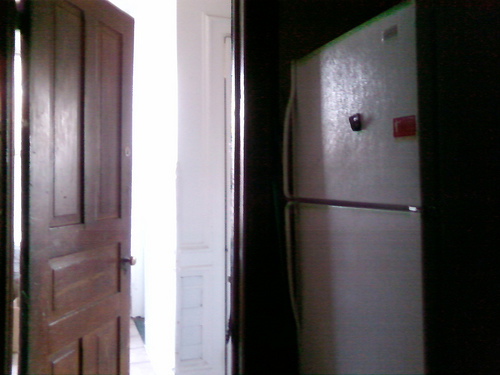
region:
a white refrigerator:
[272, 9, 424, 374]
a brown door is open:
[11, 4, 141, 374]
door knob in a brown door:
[119, 246, 144, 273]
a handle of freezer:
[273, 63, 303, 200]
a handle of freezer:
[275, 200, 308, 333]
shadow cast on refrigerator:
[270, 40, 355, 372]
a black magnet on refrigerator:
[336, 105, 371, 140]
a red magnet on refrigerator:
[386, 109, 422, 145]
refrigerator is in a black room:
[243, 6, 492, 373]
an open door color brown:
[11, 6, 139, 373]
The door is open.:
[31, 12, 161, 372]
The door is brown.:
[37, 86, 134, 373]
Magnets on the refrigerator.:
[334, 102, 427, 157]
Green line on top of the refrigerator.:
[286, 0, 436, 78]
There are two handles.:
[263, 95, 313, 321]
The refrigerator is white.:
[291, 54, 441, 374]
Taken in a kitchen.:
[8, 9, 496, 374]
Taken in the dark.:
[232, 7, 494, 373]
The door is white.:
[175, 23, 229, 363]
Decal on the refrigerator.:
[369, 14, 420, 59]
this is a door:
[20, 94, 126, 370]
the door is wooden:
[17, 110, 128, 373]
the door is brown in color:
[26, 140, 121, 370]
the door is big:
[22, 111, 132, 371]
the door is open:
[28, 6, 225, 370]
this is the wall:
[142, 3, 217, 211]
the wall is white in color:
[154, 222, 175, 257]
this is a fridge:
[283, 50, 436, 367]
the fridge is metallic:
[315, 261, 411, 353]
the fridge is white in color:
[321, 251, 391, 334]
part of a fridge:
[345, 282, 382, 348]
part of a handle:
[272, 242, 312, 310]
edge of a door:
[109, 271, 138, 311]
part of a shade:
[305, 232, 387, 307]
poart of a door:
[184, 257, 219, 337]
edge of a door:
[141, 252, 175, 299]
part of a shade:
[321, 255, 374, 322]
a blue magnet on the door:
[332, 105, 371, 140]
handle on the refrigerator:
[280, 210, 297, 335]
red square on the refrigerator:
[385, 108, 421, 140]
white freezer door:
[299, 74, 343, 186]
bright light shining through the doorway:
[141, 66, 177, 277]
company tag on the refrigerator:
[379, 18, 404, 45]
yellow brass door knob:
[126, 252, 144, 272]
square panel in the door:
[56, 22, 86, 218]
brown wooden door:
[38, 11, 137, 373]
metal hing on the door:
[406, 204, 426, 211]